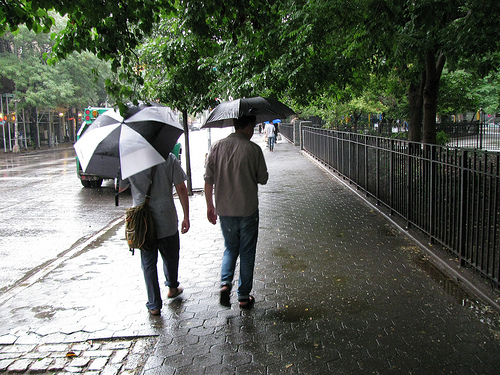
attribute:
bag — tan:
[127, 160, 157, 256]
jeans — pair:
[214, 213, 259, 293]